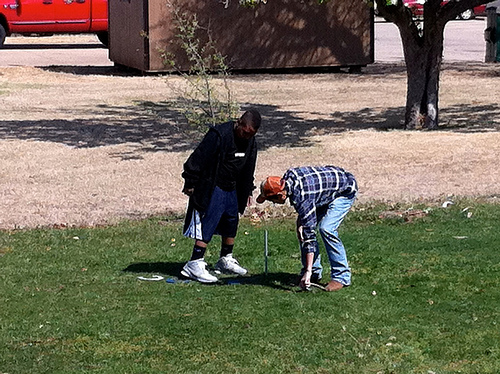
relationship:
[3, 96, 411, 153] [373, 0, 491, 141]
shadow beside tree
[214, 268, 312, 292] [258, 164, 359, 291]
shadow of a person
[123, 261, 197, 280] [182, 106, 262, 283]
shadow of a person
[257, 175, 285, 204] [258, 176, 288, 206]
cap on head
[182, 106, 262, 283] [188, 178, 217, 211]
person has pocket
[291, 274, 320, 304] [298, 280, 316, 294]
ground being touched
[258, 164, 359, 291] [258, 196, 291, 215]
man looking down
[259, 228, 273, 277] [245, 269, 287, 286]
pole in ground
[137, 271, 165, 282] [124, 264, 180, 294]
horseshoe on ground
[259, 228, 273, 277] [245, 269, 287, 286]
stake in ground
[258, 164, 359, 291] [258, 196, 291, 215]
person looking down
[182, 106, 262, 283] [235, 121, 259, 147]
person looking down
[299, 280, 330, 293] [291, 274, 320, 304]
horseshoe on ground